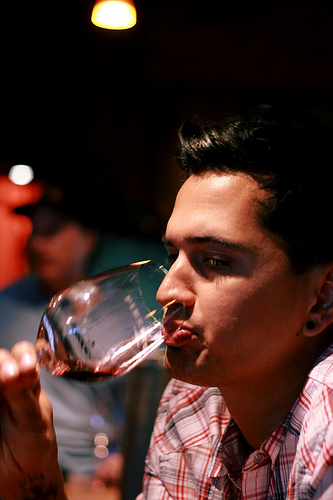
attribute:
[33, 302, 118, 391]
wine — red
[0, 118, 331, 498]
man — drinking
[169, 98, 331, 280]
hair — dark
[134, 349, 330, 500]
shirt — button-down, plaid, red, blue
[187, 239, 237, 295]
eye — brown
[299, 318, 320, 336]
earring — black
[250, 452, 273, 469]
button — transparent